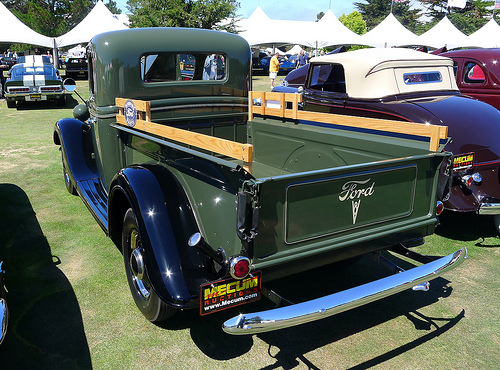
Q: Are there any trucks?
A: Yes, there is a truck.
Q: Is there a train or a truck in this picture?
A: Yes, there is a truck.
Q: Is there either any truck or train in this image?
A: Yes, there is a truck.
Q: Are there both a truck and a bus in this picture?
A: No, there is a truck but no buses.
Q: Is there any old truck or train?
A: Yes, there is an old truck.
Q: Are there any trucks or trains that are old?
A: Yes, the truck is old.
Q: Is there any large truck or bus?
A: Yes, there is a large truck.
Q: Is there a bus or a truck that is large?
A: Yes, the truck is large.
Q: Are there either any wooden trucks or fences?
A: Yes, there is a wood truck.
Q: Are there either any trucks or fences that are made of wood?
A: Yes, the truck is made of wood.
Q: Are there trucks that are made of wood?
A: Yes, there is a truck that is made of wood.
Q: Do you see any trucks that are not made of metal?
A: Yes, there is a truck that is made of wood.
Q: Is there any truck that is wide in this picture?
A: Yes, there is a wide truck.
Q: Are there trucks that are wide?
A: Yes, there is a truck that is wide.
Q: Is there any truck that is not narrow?
A: Yes, there is a wide truck.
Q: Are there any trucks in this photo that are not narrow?
A: Yes, there is a wide truck.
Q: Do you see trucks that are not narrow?
A: Yes, there is a wide truck.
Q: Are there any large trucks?
A: Yes, there is a large truck.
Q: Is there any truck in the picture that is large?
A: Yes, there is a truck that is large.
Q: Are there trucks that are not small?
A: Yes, there is a large truck.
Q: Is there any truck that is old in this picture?
A: Yes, there is an old truck.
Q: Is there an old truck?
A: Yes, there is an old truck.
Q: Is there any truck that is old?
A: Yes, there is a truck that is old.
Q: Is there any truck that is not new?
A: Yes, there is a old truck.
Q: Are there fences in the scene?
A: No, there are no fences.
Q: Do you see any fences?
A: No, there are no fences.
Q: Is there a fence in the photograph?
A: No, there are no fences.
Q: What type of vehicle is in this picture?
A: The vehicle is a truck.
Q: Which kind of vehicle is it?
A: The vehicle is a truck.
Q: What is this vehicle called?
A: This is a truck.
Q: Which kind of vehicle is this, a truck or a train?
A: This is a truck.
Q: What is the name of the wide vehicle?
A: The vehicle is a truck.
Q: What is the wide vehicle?
A: The vehicle is a truck.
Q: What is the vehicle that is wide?
A: The vehicle is a truck.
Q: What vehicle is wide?
A: The vehicle is a truck.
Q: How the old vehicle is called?
A: The vehicle is a truck.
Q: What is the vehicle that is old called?
A: The vehicle is a truck.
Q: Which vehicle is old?
A: The vehicle is a truck.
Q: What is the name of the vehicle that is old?
A: The vehicle is a truck.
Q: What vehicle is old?
A: The vehicle is a truck.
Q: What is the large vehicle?
A: The vehicle is a truck.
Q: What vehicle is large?
A: The vehicle is a truck.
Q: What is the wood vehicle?
A: The vehicle is a truck.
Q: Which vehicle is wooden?
A: The vehicle is a truck.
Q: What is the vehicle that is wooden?
A: The vehicle is a truck.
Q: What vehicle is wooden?
A: The vehicle is a truck.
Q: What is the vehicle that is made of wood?
A: The vehicle is a truck.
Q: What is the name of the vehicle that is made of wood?
A: The vehicle is a truck.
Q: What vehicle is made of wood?
A: The vehicle is a truck.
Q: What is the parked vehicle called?
A: The vehicle is a truck.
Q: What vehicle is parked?
A: The vehicle is a truck.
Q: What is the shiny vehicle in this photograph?
A: The vehicle is a truck.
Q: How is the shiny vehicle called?
A: The vehicle is a truck.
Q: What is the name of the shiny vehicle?
A: The vehicle is a truck.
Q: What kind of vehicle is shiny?
A: The vehicle is a truck.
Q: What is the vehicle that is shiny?
A: The vehicle is a truck.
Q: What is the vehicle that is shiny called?
A: The vehicle is a truck.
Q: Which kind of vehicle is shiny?
A: The vehicle is a truck.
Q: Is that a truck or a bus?
A: That is a truck.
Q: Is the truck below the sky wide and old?
A: Yes, the truck is wide and old.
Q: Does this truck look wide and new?
A: No, the truck is wide but old.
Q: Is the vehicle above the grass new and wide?
A: No, the truck is wide but old.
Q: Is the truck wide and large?
A: Yes, the truck is wide and large.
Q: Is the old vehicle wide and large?
A: Yes, the truck is wide and large.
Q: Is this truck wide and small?
A: No, the truck is wide but large.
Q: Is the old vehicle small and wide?
A: No, the truck is wide but large.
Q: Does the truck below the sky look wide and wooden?
A: Yes, the truck is wide and wooden.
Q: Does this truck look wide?
A: Yes, the truck is wide.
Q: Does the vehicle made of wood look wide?
A: Yes, the truck is wide.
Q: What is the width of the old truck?
A: The truck is wide.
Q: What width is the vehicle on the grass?
A: The truck is wide.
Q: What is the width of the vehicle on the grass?
A: The truck is wide.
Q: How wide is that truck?
A: The truck is wide.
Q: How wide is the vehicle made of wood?
A: The truck is wide.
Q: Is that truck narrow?
A: No, the truck is wide.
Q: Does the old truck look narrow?
A: No, the truck is wide.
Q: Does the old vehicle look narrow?
A: No, the truck is wide.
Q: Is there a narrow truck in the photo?
A: No, there is a truck but it is wide.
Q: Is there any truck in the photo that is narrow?
A: No, there is a truck but it is wide.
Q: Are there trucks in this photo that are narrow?
A: No, there is a truck but it is wide.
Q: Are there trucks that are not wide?
A: No, there is a truck but it is wide.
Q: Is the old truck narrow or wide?
A: The truck is wide.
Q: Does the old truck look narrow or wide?
A: The truck is wide.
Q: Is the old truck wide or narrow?
A: The truck is wide.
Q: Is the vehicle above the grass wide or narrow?
A: The truck is wide.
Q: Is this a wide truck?
A: Yes, this is a wide truck.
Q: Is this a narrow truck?
A: No, this is a wide truck.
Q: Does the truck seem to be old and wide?
A: Yes, the truck is old and wide.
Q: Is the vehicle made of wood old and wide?
A: Yes, the truck is old and wide.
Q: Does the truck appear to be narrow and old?
A: No, the truck is old but wide.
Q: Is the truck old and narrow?
A: No, the truck is old but wide.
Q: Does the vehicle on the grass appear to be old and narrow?
A: No, the truck is old but wide.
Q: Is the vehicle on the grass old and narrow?
A: No, the truck is old but wide.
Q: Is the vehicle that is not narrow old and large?
A: Yes, the truck is old and large.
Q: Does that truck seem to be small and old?
A: No, the truck is old but large.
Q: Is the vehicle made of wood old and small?
A: No, the truck is old but large.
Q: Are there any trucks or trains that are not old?
A: No, there is a truck but it is old.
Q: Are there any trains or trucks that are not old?
A: No, there is a truck but it is old.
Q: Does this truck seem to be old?
A: Yes, the truck is old.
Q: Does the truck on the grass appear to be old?
A: Yes, the truck is old.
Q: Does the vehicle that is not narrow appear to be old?
A: Yes, the truck is old.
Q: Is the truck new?
A: No, the truck is old.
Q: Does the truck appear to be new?
A: No, the truck is old.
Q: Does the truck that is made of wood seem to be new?
A: No, the truck is old.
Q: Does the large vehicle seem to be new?
A: No, the truck is old.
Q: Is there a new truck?
A: No, there is a truck but it is old.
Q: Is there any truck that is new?
A: No, there is a truck but it is old.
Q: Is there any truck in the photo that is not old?
A: No, there is a truck but it is old.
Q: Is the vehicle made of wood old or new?
A: The truck is old.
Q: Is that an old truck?
A: Yes, that is an old truck.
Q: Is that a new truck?
A: No, that is an old truck.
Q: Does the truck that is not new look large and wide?
A: Yes, the truck is large and wide.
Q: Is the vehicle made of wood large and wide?
A: Yes, the truck is large and wide.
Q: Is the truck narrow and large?
A: No, the truck is large but wide.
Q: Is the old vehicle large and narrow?
A: No, the truck is large but wide.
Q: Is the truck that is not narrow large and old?
A: Yes, the truck is large and old.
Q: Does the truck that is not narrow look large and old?
A: Yes, the truck is large and old.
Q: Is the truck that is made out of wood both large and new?
A: No, the truck is large but old.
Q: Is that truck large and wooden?
A: Yes, the truck is large and wooden.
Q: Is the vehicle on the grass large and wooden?
A: Yes, the truck is large and wooden.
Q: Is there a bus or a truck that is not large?
A: No, there is a truck but it is large.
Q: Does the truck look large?
A: Yes, the truck is large.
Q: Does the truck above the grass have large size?
A: Yes, the truck is large.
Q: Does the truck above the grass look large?
A: Yes, the truck is large.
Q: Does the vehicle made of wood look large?
A: Yes, the truck is large.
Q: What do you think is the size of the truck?
A: The truck is large.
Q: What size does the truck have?
A: The truck has large size.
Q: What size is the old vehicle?
A: The truck is large.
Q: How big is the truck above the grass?
A: The truck is large.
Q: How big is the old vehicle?
A: The truck is large.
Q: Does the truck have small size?
A: No, the truck is large.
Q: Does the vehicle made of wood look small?
A: No, the truck is large.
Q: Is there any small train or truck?
A: No, there is a truck but it is large.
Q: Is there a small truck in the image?
A: No, there is a truck but it is large.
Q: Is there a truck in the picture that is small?
A: No, there is a truck but it is large.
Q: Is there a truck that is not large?
A: No, there is a truck but it is large.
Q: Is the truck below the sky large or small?
A: The truck is large.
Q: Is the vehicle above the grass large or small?
A: The truck is large.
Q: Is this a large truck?
A: Yes, this is a large truck.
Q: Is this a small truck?
A: No, this is a large truck.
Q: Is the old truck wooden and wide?
A: Yes, the truck is wooden and wide.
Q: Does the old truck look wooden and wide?
A: Yes, the truck is wooden and wide.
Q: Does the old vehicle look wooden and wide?
A: Yes, the truck is wooden and wide.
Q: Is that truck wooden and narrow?
A: No, the truck is wooden but wide.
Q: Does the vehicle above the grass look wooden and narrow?
A: No, the truck is wooden but wide.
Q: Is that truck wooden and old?
A: Yes, the truck is wooden and old.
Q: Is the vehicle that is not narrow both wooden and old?
A: Yes, the truck is wooden and old.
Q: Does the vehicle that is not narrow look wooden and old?
A: Yes, the truck is wooden and old.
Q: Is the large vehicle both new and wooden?
A: No, the truck is wooden but old.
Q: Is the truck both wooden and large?
A: Yes, the truck is wooden and large.